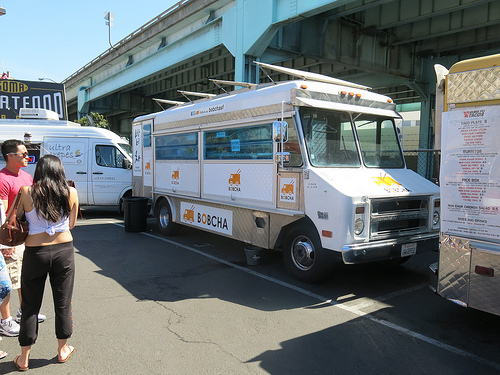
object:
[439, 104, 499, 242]
menu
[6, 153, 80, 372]
woman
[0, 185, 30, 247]
purse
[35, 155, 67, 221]
hair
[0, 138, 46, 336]
man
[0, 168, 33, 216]
pink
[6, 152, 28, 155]
sunglasses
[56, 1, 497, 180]
overpass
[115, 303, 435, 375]
ground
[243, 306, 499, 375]
shadow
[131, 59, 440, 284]
truck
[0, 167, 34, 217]
shirt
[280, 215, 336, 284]
tire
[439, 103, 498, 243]
sign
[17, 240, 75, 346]
pants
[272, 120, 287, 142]
mirror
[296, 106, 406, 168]
windshield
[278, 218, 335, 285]
wheel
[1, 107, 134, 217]
car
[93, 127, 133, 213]
front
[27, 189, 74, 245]
back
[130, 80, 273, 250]
side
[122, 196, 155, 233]
bin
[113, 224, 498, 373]
line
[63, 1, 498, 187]
bridge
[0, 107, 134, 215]
van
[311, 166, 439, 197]
hood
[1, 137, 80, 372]
people